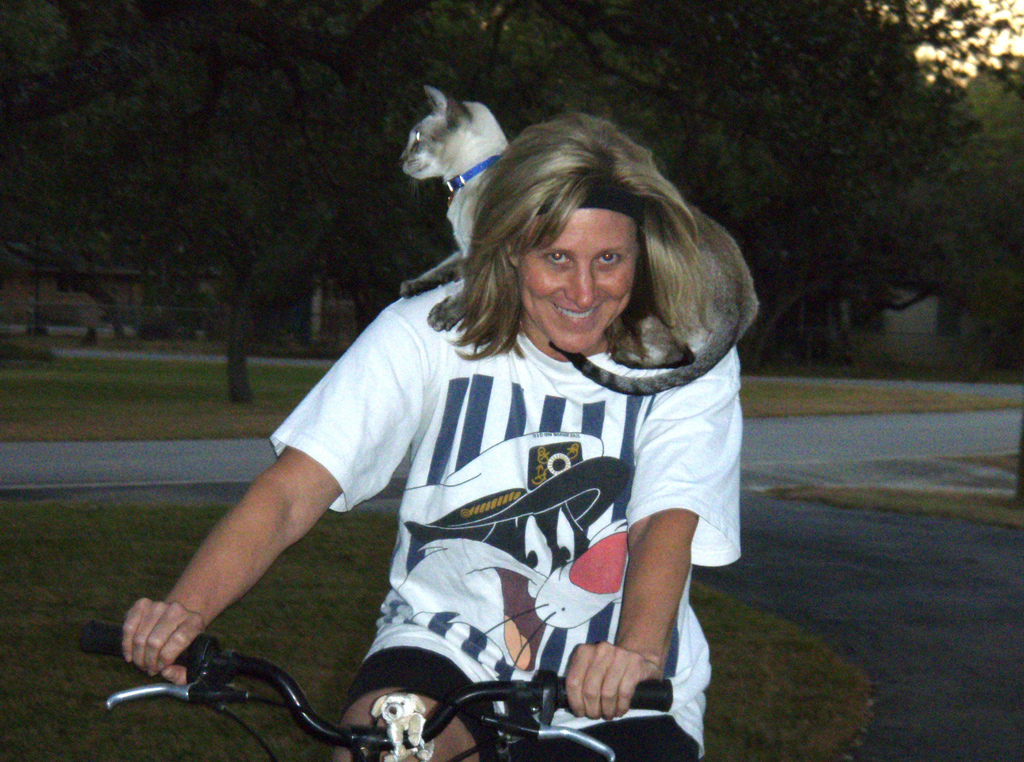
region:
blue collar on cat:
[446, 151, 510, 194]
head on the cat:
[401, 87, 519, 182]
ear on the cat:
[441, 96, 468, 134]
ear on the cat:
[414, 81, 446, 113]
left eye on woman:
[585, 239, 618, 271]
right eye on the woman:
[542, 240, 572, 269]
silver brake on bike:
[87, 659, 214, 721]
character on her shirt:
[424, 438, 633, 689]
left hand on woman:
[553, 624, 672, 724]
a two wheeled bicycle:
[36, 582, 678, 756]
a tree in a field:
[64, 11, 347, 413]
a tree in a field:
[459, 4, 693, 123]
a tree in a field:
[686, 16, 950, 372]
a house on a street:
[2, 231, 353, 361]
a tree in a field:
[9, 216, 73, 350]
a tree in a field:
[688, 128, 800, 364]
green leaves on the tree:
[753, 150, 805, 193]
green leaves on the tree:
[948, 201, 994, 255]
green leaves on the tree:
[797, 53, 899, 115]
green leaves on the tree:
[690, 78, 786, 149]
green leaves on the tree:
[297, 121, 340, 180]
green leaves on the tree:
[196, 287, 266, 326]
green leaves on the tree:
[94, 59, 171, 167]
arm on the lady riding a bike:
[174, 351, 408, 624]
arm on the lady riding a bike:
[610, 416, 703, 647]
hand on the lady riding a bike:
[121, 581, 201, 693]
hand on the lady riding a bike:
[551, 636, 662, 731]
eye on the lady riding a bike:
[535, 244, 578, 270]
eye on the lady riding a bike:
[589, 249, 624, 266]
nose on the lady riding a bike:
[566, 256, 596, 310]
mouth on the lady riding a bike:
[551, 294, 612, 326]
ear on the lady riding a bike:
[500, 236, 516, 269]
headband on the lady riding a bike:
[529, 161, 641, 220]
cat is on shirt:
[388, 412, 645, 668]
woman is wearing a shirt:
[251, 244, 745, 748]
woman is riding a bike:
[81, 567, 693, 757]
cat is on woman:
[377, 82, 767, 396]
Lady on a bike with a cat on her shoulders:
[73, 80, 754, 758]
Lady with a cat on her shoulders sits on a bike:
[84, 76, 764, 756]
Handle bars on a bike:
[81, 613, 674, 759]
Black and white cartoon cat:
[394, 423, 638, 680]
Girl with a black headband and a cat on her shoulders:
[82, 82, 747, 754]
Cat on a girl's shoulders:
[398, 83, 759, 393]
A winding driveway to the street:
[698, 484, 1016, 759]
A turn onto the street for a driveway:
[739, 404, 1015, 759]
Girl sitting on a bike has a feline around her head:
[87, 85, 755, 753]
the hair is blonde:
[385, 104, 816, 367]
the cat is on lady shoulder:
[307, 9, 862, 443]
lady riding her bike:
[59, 38, 818, 746]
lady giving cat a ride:
[62, 94, 761, 750]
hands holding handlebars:
[0, 572, 697, 756]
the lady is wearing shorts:
[291, 623, 783, 757]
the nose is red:
[556, 483, 667, 602]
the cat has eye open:
[369, 29, 494, 200]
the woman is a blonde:
[449, 108, 735, 369]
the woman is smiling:
[552, 297, 603, 324]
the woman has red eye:
[544, 247, 617, 264]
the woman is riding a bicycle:
[92, 88, 747, 753]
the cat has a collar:
[441, 145, 514, 204]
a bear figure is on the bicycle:
[376, 690, 441, 758]